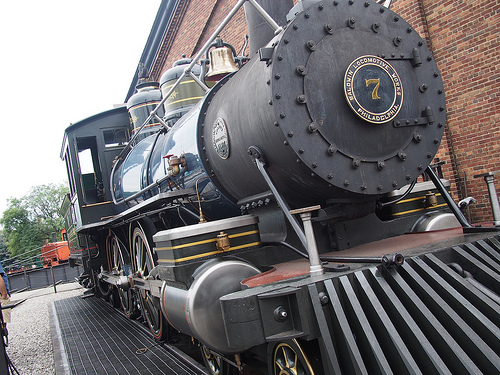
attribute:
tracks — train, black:
[85, 289, 209, 374]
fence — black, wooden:
[6, 259, 56, 285]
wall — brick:
[156, 0, 499, 227]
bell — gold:
[201, 38, 242, 79]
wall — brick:
[124, 3, 495, 224]